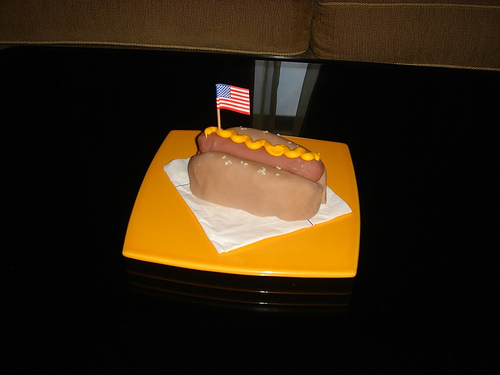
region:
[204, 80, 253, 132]
flag is American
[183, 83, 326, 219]
American flag is on hot dog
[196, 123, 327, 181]
hot dog has mustard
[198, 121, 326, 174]
mustard on the hot dog is yellow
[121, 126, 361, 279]
hot dog is on yellow plate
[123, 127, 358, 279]
yellow plate is a square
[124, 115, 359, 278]
napkin is on yellow plate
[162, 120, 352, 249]
hot dog is on the napkin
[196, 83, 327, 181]
flag is on the hotdog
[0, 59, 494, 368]
yellow plate is on a black surface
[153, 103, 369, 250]
a fake hot dog on a yellow plate on a black table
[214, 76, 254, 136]
a tiny American flag on a toothpick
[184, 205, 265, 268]
the corner of a white paper napkin under the hot dog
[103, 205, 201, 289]
the corner of the yellow square plate the hot dog is on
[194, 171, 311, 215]
the light brown hot dog bun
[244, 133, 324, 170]
a swirled line of mustard on top of the hot dog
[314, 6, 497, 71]
a brown cushion on a piece of furniture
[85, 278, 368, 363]
a black shiny surface the plate is on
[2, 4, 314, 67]
a brown cushion from a sofa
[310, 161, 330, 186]
the pink round end of the hot dog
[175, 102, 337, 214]
A cake shaped like a hot dog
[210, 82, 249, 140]
an american flag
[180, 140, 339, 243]
white napkin the cake is resting on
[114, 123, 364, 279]
a yellow plate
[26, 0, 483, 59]
some brown cushions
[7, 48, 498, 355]
A black table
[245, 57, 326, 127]
a reflection of a window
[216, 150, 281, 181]
fake sesame seeds on the cake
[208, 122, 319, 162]
fake mustard on the cake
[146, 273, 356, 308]
reflection of the plate on the table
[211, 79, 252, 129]
A small american flag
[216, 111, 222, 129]
A tooth pick in dessert.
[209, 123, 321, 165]
Frosting looks like cheese.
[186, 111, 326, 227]
A dessert in hot dog shape.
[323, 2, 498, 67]
A seat couch cushion.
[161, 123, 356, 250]
Food on a napkin.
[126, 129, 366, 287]
A orange plate of food.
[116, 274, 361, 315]
Reflection from the table.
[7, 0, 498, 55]
A brown colored couch.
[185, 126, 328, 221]
A hot dog and bun.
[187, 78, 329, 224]
a hot dog with mustard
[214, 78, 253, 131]
a small american flag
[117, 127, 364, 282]
a bright yellow platter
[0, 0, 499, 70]
edge of brown couch cusions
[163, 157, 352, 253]
a white napikin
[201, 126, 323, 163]
yellow swirly mustard on hot dog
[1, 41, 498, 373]
a shiny black table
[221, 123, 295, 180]
small white shavings on top of bun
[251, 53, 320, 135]
a white reflection on table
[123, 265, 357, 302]
the plate's reflection on table